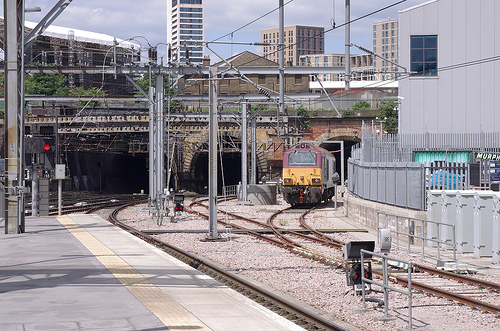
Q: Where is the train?
A: On the tracks.